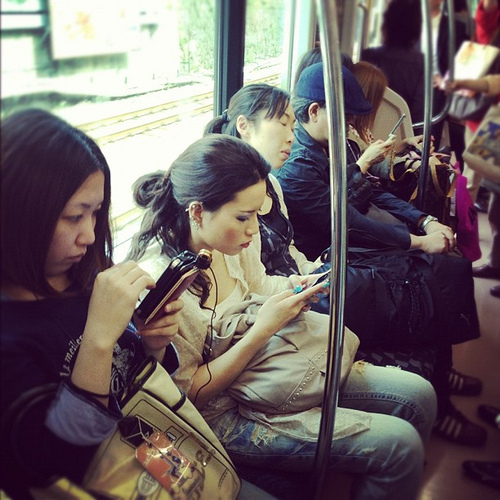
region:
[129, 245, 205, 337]
silver and black cellphone case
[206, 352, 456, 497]
woman's light blue jeans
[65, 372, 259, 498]
black and beige purse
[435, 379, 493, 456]
sneakers with white stripes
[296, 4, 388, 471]
tall steal supporting pole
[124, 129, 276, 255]
woman with ponytail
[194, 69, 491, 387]
Asian woman inside a train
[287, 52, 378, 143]
man with blue hat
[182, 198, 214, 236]
ear with lots of piecings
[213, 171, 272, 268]
face with makeup on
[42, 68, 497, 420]
Most people are looking at phone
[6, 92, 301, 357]
Women have black hair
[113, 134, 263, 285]
Woman has hair in bun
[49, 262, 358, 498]
Women have purses on lap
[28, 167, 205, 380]
Woman is looking at phone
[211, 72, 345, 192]
Woman is falling asleep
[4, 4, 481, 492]
People are on bus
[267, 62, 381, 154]
Man has blue cap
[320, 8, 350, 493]
Silver metal bus poles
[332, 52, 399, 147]
Woman has brown hair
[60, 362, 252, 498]
A cream colored bag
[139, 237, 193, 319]
A cell phone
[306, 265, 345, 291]
A cell phone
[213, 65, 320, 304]
a woman sleeping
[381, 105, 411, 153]
A cell phone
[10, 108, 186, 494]
A woman in a black shirt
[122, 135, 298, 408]
a woman in a white shirt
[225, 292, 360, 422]
a grey bag in the woman's lap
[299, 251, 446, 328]
a black bag in the sleeping woman's lap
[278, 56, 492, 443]
a man sitting down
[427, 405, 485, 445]
a black and white shoe on a foot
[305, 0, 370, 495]
a metal pole on a train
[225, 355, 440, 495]
a pair of jeans on a woman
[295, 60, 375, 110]
a black hat on a man's head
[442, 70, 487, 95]
a hand holding onto a pole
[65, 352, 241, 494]
a black and tan bag on a woman's lap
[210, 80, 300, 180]
the head of a sleeping woman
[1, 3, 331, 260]
the window of a train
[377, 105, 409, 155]
a phone in a hand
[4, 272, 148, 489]
a black shirt on a woman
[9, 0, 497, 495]
People riding public transportation.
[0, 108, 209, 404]
Woman looking at her cell phone.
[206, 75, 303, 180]
Woman taking a nap.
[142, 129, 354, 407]
Woman checking her cell phone.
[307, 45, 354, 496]
Steel bar.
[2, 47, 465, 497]
Five people seated on a train.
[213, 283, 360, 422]
Tan handbag.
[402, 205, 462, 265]
Hands crossed on knees.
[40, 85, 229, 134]
Tracks seen out of window.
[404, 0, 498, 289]
People standing in background.